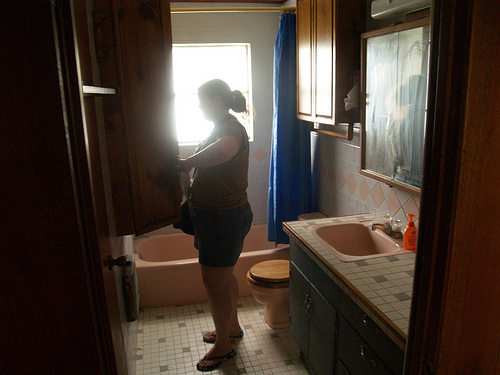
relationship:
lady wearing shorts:
[163, 61, 269, 372] [186, 199, 254, 263]